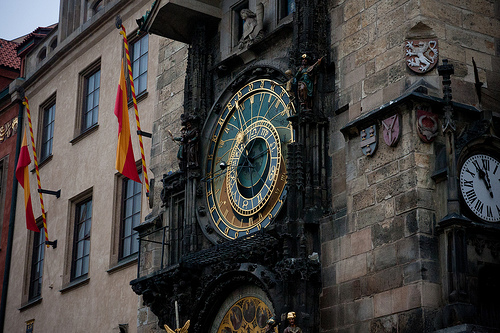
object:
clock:
[190, 57, 306, 244]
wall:
[337, 166, 420, 295]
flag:
[110, 24, 148, 205]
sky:
[8, 2, 44, 22]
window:
[72, 66, 102, 130]